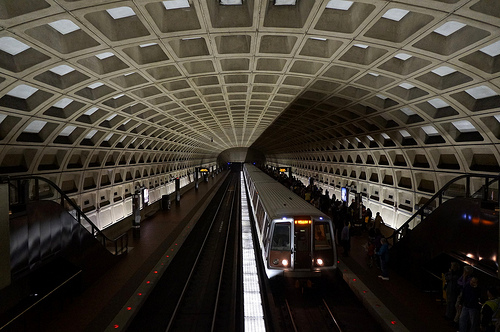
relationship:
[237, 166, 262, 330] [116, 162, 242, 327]
divider between track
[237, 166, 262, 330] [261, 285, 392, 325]
divider between track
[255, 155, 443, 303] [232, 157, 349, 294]
passengers waiting on train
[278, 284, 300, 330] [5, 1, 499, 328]
tracks in subway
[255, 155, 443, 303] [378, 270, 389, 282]
passengers wearing shoes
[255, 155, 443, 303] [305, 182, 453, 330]
passengers waiting on platform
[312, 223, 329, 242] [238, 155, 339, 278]
driver of subway train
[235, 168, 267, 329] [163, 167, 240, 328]
lights separating tracks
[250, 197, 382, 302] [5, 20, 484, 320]
subway train in station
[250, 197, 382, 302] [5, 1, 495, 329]
subway train in tunnel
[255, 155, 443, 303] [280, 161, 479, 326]
passengers waiting on platform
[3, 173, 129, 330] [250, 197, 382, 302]
staircase left of subway train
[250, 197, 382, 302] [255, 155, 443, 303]
subway train loading passengers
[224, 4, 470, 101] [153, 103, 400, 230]
cieling of subway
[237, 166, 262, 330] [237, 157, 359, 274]
divider of train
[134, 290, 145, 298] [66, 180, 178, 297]
red light on dock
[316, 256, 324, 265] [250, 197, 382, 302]
headlight on subway train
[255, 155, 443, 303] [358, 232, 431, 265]
passengers wearing shirt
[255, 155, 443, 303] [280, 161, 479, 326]
passengers at platform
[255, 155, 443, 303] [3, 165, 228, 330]
passengers at platform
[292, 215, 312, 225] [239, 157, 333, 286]
sign on train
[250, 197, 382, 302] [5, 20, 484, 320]
subway train arriving to station